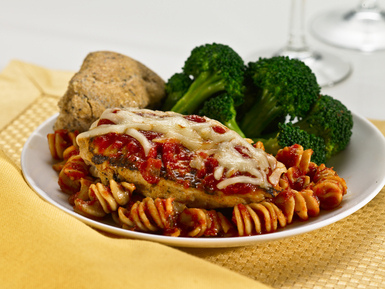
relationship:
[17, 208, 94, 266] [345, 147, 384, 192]
placemat under plate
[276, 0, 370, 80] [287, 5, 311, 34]
wineglass has stem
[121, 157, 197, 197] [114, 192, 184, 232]
chicken breast on pasta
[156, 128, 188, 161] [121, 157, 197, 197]
sauce on chicken breast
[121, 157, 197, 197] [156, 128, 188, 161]
chicken breast has sauce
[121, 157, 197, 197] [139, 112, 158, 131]
chicken breast has cheese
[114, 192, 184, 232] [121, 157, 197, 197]
pasta with chicken breast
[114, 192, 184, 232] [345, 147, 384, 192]
pasta on plate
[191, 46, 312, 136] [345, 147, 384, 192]
broccoli on plate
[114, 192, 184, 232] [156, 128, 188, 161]
pasta with sauce